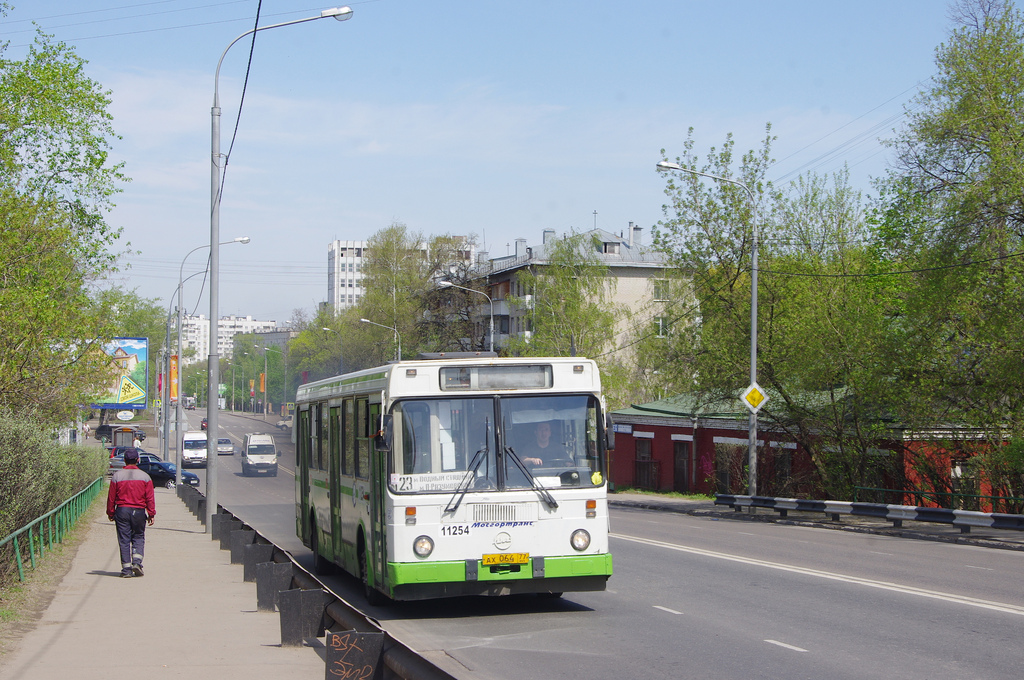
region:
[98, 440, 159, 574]
man wearing red jacket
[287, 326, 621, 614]
white and green transit bus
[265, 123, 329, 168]
white clouds in blue sky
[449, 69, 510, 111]
white clouds in blue sky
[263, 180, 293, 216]
white clouds in blue sky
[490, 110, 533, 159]
white clouds in blue sky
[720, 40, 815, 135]
white clouds in blue sky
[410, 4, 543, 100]
white clouds in blue sky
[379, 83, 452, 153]
white clouds in blue sky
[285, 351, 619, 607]
White bus with a green bumper.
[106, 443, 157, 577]
Man wearing red and gray sweater.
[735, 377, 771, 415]
Yellow traffic sign with with rim.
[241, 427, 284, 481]
Gray minivan with black bumper.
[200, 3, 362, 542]
Tall gray street light.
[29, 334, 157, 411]
Large billboard partially obstructed by leaves.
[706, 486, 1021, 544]
White and black road barrier.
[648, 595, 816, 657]
Small white stripes painted on road.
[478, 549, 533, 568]
Yellow license plate with black numbers and letters.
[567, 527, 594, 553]
Black rimmed white headlight.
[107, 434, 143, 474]
the head of a man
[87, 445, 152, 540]
the back of a man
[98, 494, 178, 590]
the legs of a man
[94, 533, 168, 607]
the feet of a man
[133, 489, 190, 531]
the hand of a man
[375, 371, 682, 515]
the windshield on a bus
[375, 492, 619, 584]
the headlights on a bus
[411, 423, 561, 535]
the windshield wipers on a bus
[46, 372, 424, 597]
a man near a bus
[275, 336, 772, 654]
a bus on the road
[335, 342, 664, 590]
front of the bus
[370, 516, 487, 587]
light on front of bus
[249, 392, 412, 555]
side of the bus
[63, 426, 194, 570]
person wearing red clothing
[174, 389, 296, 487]
cars in the distance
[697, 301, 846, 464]
sign on the pole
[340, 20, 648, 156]
sky above the land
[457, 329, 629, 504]
bus driver in the bus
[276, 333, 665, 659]
a green and white bus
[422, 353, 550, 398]
the sign of a bus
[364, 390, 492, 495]
the left windshield of a bus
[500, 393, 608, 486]
the right windshield of a bus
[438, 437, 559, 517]
the windshield wipers of a bus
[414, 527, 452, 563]
the left headlight of a bus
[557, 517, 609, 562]
the right headlight of a bus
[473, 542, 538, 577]
the license plate of a bus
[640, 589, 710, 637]
white line in the road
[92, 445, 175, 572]
a man that is walking